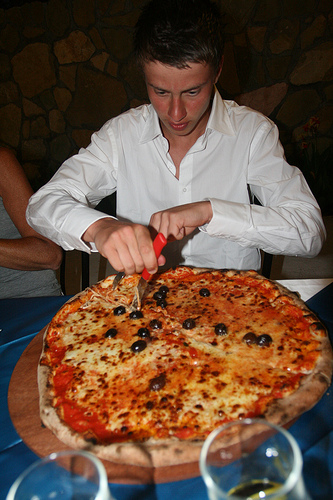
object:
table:
[0, 275, 332, 497]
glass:
[197, 415, 305, 498]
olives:
[256, 332, 272, 347]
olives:
[159, 285, 169, 295]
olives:
[215, 321, 227, 336]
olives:
[137, 327, 150, 338]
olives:
[149, 369, 166, 390]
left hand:
[86, 216, 165, 274]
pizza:
[37, 261, 331, 469]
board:
[7, 325, 296, 485]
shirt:
[26, 92, 324, 269]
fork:
[112, 271, 122, 289]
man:
[22, 11, 325, 297]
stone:
[271, 52, 288, 73]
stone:
[286, 104, 323, 124]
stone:
[78, 73, 127, 117]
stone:
[55, 32, 89, 59]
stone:
[21, 132, 51, 157]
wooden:
[10, 335, 71, 498]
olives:
[131, 338, 146, 352]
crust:
[33, 264, 331, 468]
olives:
[149, 318, 162, 329]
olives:
[200, 288, 210, 297]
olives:
[152, 290, 164, 299]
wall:
[0, 3, 322, 220]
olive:
[157, 297, 169, 309]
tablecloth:
[1, 288, 333, 498]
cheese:
[38, 266, 322, 445]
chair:
[3, 195, 86, 297]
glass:
[6, 442, 109, 499]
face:
[149, 59, 212, 137]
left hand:
[149, 198, 211, 243]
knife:
[129, 231, 167, 311]